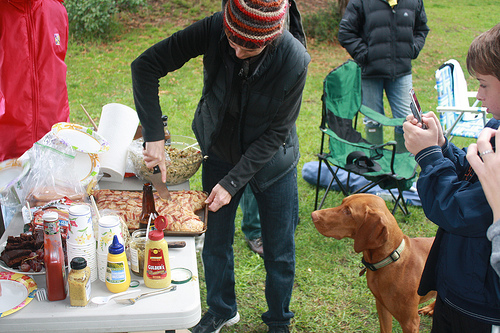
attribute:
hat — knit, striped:
[222, 2, 289, 44]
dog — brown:
[306, 187, 442, 332]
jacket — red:
[0, 2, 70, 159]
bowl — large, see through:
[123, 140, 205, 190]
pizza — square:
[99, 190, 203, 229]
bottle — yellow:
[103, 235, 133, 292]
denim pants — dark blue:
[201, 159, 298, 324]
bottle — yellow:
[101, 232, 134, 297]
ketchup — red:
[35, 206, 70, 305]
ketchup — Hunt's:
[19, 195, 80, 293]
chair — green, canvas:
[309, 55, 419, 228]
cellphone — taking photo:
[389, 85, 434, 133]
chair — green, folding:
[321, 59, 423, 207]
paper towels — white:
[96, 102, 139, 182]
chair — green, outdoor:
[316, 58, 432, 218]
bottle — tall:
[38, 210, 69, 301]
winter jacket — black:
[338, 8, 434, 85]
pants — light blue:
[355, 70, 419, 185]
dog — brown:
[322, 186, 436, 328]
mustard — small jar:
[64, 253, 95, 308]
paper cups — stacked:
[95, 214, 114, 291]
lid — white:
[42, 211, 59, 219]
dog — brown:
[312, 186, 417, 329]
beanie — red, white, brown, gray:
[227, 0, 287, 42]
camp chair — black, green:
[310, 57, 412, 221]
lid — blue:
[107, 233, 123, 255]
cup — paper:
[63, 203, 95, 244]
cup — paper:
[94, 210, 126, 256]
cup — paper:
[64, 243, 94, 247]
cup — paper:
[67, 250, 95, 254]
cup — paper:
[98, 254, 109, 258]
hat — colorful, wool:
[221, 1, 287, 48]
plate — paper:
[3, 155, 32, 193]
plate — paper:
[10, 181, 26, 207]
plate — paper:
[46, 148, 102, 191]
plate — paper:
[50, 120, 109, 154]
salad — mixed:
[131, 142, 201, 184]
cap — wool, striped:
[219, 1, 289, 50]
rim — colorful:
[3, 268, 40, 318]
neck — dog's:
[361, 226, 409, 271]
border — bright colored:
[7, 262, 38, 286]